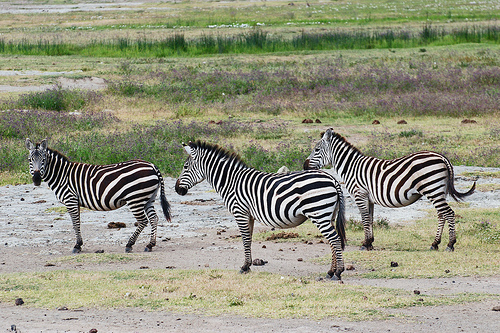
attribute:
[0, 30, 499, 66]
grass — green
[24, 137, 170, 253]
zebra — standing, here, looking, black, white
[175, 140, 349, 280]
zebra — standing, here, black, white, looking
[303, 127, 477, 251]
zebra — standing, here, black, white, looking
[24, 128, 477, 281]
zebras — white, black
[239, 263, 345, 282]
hooves — black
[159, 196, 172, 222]
tail — black, long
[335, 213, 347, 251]
tail — black, long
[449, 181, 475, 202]
tail — black, curved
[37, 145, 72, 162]
mane — black, thick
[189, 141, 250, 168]
mane — black, thick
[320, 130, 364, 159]
mane — black, thick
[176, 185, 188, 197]
mouth — black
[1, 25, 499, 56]
reeds — tall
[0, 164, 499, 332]
dirt — dry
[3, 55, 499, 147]
some grass — brown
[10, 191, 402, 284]
clumps — dark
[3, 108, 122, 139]
flowers — purple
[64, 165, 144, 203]
stripes — black, white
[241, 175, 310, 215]
stripes — black, white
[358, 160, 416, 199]
stripes — black, white